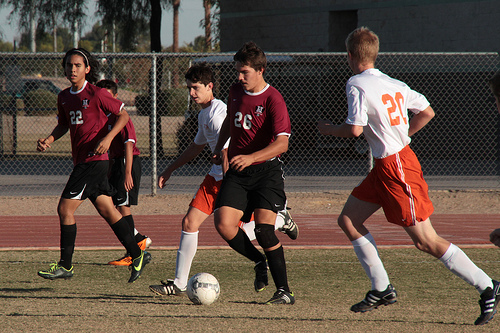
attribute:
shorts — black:
[210, 163, 289, 218]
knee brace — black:
[250, 217, 281, 251]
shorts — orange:
[344, 152, 458, 233]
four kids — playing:
[35, 48, 150, 285]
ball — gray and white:
[185, 272, 220, 307]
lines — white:
[363, 292, 382, 308]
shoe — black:
[304, 262, 419, 320]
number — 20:
[376, 88, 411, 130]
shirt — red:
[340, 71, 431, 160]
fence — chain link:
[90, 23, 498, 223]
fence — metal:
[3, 50, 495, 197]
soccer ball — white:
[185, 272, 222, 306]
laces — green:
[42, 257, 58, 277]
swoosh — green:
[127, 255, 151, 276]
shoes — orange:
[136, 240, 145, 248]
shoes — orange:
[116, 256, 125, 265]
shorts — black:
[218, 153, 291, 216]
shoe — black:
[123, 254, 152, 281]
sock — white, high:
[165, 227, 200, 290]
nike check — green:
[130, 252, 143, 272]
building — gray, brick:
[217, 0, 498, 159]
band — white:
[72, 47, 90, 67]